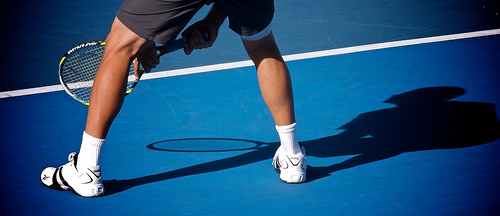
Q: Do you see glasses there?
A: No, there are no glasses.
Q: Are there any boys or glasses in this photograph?
A: No, there are no glasses or boys.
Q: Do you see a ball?
A: No, there are no balls.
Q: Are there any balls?
A: No, there are no balls.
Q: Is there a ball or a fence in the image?
A: No, there are no balls or fences.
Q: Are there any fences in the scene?
A: No, there are no fences.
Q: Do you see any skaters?
A: No, there are no skaters.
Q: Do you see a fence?
A: No, there are no fences.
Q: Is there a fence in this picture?
A: No, there are no fences.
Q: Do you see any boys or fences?
A: No, there are no fences or boys.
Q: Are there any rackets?
A: Yes, there is a racket.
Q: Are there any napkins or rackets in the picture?
A: Yes, there is a racket.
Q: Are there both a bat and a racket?
A: No, there is a racket but no bats.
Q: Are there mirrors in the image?
A: No, there are no mirrors.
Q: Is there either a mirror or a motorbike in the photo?
A: No, there are no mirrors or motorcycles.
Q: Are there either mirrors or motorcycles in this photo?
A: No, there are no mirrors or motorcycles.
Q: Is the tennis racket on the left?
A: Yes, the tennis racket is on the left of the image.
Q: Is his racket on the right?
A: No, the tennis racket is on the left of the image.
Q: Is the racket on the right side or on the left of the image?
A: The racket is on the left of the image.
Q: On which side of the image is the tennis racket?
A: The tennis racket is on the left of the image.